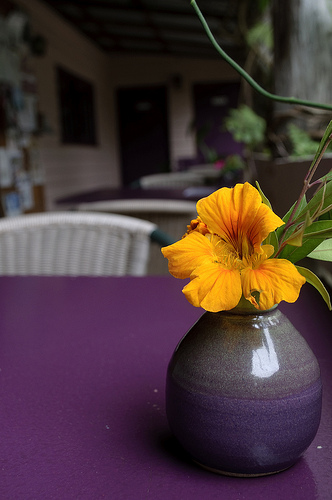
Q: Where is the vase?
A: On the table.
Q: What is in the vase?
A: Flower.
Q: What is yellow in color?
A: Flower.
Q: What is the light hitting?
A: The vase.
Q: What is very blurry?
A: The background.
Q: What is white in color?
A: The chair.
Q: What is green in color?
A: The leaves.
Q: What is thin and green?
A: The stem.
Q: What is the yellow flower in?
A: A purple flower vase.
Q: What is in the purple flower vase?
A: A yellow flower.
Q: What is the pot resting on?
A: A table.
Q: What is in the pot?
A: A flower.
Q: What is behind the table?
A: A chair.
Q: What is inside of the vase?
A: A flower.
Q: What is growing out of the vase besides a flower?
A: A stem.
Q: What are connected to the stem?
A: Leaves?.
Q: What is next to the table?
A: A seat.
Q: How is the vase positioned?
A: Upright.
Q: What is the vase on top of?
A: A table.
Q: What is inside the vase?
A: A flower.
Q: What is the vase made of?
A: Porcelain.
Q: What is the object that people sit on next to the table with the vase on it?
A: A chair.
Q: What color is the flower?
A: Yellow.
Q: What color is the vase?
A: Purple.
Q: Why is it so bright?
A: Lamp.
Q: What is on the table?
A: The vase.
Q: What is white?
A: The chair.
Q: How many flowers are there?
A: One.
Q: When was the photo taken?
A: Day time.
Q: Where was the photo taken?
A: Near flowers.